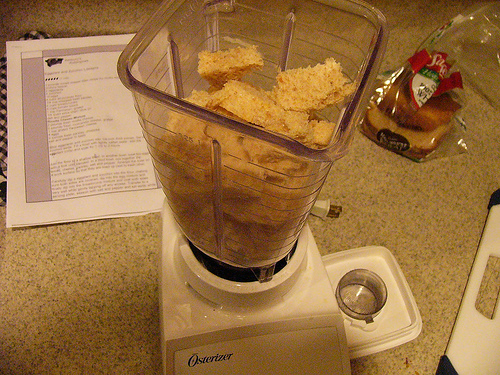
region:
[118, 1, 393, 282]
blender jar is clear plastic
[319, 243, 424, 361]
top of blender jar next to blender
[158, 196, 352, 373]
base of blender is white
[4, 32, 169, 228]
sheet pf paper next to blender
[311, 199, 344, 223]
electrical plug behind blender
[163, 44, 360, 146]
pieces of bread inside blender jar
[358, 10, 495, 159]
plastic bag to the right of blender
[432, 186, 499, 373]
white cutting board to the right of blender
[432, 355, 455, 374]
black corner of white cutting board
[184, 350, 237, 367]
logo on blender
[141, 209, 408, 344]
Food blender and lid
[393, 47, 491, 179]
Open loaf of bread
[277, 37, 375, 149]
Bread crumbs in blender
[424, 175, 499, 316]
Cutting board on kitchen counter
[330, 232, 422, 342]
Blender lid on kitchen counter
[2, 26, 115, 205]
Recipe in a book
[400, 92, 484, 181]
Loaf of bread on a counter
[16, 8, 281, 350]
Repice and bread in blender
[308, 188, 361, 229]
Blender plug in on kitchen counter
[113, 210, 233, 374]
Blender sitting on kitchen counter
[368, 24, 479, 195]
open bag of bread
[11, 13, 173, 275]
paperwork on counter in photo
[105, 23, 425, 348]
bread pieces in blender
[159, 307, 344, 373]
blue writing on food processor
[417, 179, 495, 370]
black and white cutting board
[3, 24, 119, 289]
checkered cloth under paperwork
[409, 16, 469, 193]
red green white on bag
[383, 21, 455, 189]
writing on bag of bread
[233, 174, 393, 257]
power cord of blender seen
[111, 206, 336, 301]
black ring around bottom of blender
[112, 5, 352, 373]
white blender with food inside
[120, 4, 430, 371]
lid next to blender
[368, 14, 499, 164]
open bread bag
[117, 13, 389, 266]
brown bread in blender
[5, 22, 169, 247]
black print on white paper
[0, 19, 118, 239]
blue towel under book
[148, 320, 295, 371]
blue letters on kitchen appliance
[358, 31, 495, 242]
bread on kitchen counter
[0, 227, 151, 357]
grey, black and white speckled counter top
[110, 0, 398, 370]
Blender is white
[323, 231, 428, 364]
Lid of blender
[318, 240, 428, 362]
Lid is white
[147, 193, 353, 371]
Motor of blender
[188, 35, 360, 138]
Bread in pieces on blender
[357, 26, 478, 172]
Bread in a bag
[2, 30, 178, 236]
Piece of paper on counter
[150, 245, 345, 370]
Brand of blender is "Osterizer"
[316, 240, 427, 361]
Lid of blender is white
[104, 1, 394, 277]
Jar of blender is glass